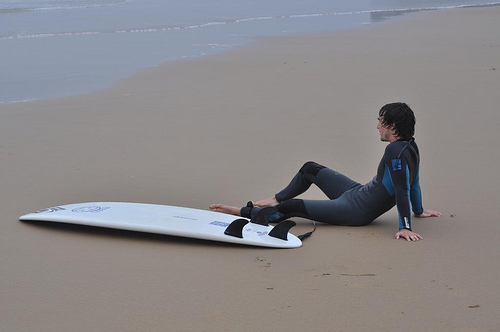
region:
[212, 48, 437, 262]
a surfer resting on the beach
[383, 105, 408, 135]
wet black hair on head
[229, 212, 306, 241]
black fins on the surfboard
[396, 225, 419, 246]
a hand on the wet sand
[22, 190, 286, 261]
a white surfboard on the sand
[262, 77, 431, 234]
a surfer wearing a dark blue wetsuit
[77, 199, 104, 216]
a logo on the board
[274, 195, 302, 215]
a black patch on the knee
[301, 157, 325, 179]
black patch on the knew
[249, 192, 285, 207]
bare foot on the sand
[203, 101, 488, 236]
sufer on the beach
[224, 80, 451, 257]
sufer wearing black and blue wet suit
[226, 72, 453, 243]
man wearing black and blue wet suit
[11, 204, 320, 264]
surf board on beach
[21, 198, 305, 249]
white surf board with black fins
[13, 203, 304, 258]
white surfboard and black fins on beach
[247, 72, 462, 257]
man sitting on beach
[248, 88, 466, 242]
man in wet suit sitting on beach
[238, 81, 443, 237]
man in black and blue wet suit sitting beach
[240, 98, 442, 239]
man looking at water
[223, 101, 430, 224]
a surfer in a full black wetsuit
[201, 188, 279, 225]
the surfer has bare feet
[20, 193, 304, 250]
the surfboard is upside down on the beach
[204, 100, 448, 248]
the surfer is resting on the beach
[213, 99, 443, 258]
the man is watching the waves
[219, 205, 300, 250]
the surfboard has three skegs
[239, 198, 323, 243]
the surfboard is tethered to the man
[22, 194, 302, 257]
the board is white with black skegs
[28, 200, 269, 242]
some markings are on the board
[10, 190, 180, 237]
A surfboard in the photo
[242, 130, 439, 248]
Surfwear in the photo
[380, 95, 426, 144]
Black hair in the photo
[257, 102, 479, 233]
A man on the sand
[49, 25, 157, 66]
Ocean waters in the photo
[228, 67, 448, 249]
A man lying on the sand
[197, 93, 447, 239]
A man looking at the sea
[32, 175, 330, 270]
A surfboard lying on the beach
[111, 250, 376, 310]
Brown sand of the beach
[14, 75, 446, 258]
man sitting on sand of beach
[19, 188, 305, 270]
white surfboard on beach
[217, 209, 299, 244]
black shark fin shaped protrusions on surfboard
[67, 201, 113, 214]
black circle logo white surfboard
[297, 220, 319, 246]
black tether cord on surfboard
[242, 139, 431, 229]
black and blue wet suit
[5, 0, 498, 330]
tan beach sand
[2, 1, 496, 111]
edge of body of water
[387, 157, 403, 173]
blue patch on shoulder of wetsuit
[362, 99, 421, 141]
man with wet hair